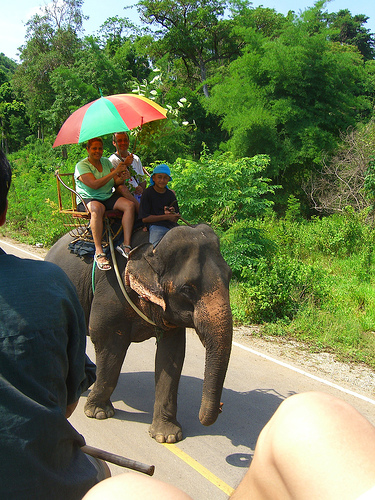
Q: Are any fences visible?
A: No, there are no fences.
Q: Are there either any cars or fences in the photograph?
A: No, there are no fences or cars.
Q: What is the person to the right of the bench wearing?
A: The person is wearing a cap.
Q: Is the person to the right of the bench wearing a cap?
A: Yes, the person is wearing a cap.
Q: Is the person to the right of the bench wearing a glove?
A: No, the person is wearing a cap.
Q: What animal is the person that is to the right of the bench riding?
A: The person is riding an elephant.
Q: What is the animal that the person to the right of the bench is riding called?
A: The animal is an elephant.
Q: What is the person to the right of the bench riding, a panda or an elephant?
A: The person is riding an elephant.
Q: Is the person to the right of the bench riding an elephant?
A: Yes, the person is riding an elephant.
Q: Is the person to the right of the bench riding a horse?
A: No, the person is riding an elephant.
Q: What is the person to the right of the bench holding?
A: The person is holding the stick.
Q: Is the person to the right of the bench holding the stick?
A: Yes, the person is holding the stick.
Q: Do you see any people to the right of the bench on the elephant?
A: Yes, there is a person to the right of the bench.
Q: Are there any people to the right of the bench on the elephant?
A: Yes, there is a person to the right of the bench.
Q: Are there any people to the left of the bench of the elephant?
A: No, the person is to the right of the bench.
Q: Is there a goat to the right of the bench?
A: No, there is a person to the right of the bench.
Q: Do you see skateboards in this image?
A: No, there are no skateboards.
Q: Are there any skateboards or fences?
A: No, there are no skateboards or fences.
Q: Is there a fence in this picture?
A: No, there are no fences.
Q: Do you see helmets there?
A: No, there are no helmets.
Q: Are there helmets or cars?
A: No, there are no helmets or cars.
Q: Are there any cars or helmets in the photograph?
A: No, there are no helmets or cars.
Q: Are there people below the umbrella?
A: Yes, there is a person below the umbrella.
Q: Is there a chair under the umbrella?
A: No, there is a person under the umbrella.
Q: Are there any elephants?
A: Yes, there is an elephant.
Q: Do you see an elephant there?
A: Yes, there is an elephant.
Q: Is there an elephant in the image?
A: Yes, there is an elephant.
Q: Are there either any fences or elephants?
A: Yes, there is an elephant.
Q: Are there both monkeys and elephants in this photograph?
A: No, there is an elephant but no monkeys.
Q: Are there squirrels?
A: No, there are no squirrels.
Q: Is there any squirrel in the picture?
A: No, there are no squirrels.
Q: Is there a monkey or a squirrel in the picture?
A: No, there are no squirrels or monkeys.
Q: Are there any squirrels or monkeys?
A: No, there are no squirrels or monkeys.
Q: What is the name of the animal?
A: The animal is an elephant.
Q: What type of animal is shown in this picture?
A: The animal is an elephant.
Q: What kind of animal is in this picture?
A: The animal is an elephant.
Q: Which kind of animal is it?
A: The animal is an elephant.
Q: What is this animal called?
A: That is an elephant.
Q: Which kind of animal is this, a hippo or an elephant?
A: That is an elephant.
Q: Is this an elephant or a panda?
A: This is an elephant.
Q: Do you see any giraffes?
A: No, there are no giraffes.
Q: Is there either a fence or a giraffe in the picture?
A: No, there are no giraffes or fences.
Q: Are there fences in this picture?
A: No, there are no fences.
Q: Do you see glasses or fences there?
A: No, there are no fences or glasses.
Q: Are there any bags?
A: No, there are no bags.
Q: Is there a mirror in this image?
A: No, there are no mirrors.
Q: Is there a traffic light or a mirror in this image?
A: No, there are no mirrors or traffic lights.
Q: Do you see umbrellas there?
A: Yes, there is an umbrella.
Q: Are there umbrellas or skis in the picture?
A: Yes, there is an umbrella.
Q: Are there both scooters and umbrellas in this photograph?
A: No, there is an umbrella but no scooters.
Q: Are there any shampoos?
A: No, there are no shampoos.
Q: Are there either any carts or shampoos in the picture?
A: No, there are no shampoos or carts.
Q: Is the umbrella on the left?
A: Yes, the umbrella is on the left of the image.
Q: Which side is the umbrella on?
A: The umbrella is on the left of the image.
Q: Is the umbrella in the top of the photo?
A: Yes, the umbrella is in the top of the image.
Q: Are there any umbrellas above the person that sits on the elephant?
A: Yes, there is an umbrella above the person.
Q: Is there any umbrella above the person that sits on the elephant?
A: Yes, there is an umbrella above the person.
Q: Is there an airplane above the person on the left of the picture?
A: No, there is an umbrella above the person.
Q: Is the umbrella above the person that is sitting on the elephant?
A: Yes, the umbrella is above the person.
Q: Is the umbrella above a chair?
A: No, the umbrella is above the person.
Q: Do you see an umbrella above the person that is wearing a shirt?
A: Yes, there is an umbrella above the person.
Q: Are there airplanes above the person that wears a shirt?
A: No, there is an umbrella above the person.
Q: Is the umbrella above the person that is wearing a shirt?
A: Yes, the umbrella is above the person.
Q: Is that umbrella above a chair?
A: No, the umbrella is above the person.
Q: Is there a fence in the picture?
A: No, there are no fences.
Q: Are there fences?
A: No, there are no fences.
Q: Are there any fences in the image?
A: No, there are no fences.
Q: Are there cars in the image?
A: No, there are no cars.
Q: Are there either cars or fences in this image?
A: No, there are no cars or fences.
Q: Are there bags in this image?
A: No, there are no bags.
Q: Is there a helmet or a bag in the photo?
A: No, there are no bags or helmets.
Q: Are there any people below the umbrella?
A: Yes, there is a person below the umbrella.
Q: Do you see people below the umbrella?
A: Yes, there is a person below the umbrella.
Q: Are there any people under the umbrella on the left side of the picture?
A: Yes, there is a person under the umbrella.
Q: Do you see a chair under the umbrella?
A: No, there is a person under the umbrella.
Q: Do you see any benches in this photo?
A: Yes, there is a bench.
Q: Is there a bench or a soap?
A: Yes, there is a bench.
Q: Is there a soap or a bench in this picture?
A: Yes, there is a bench.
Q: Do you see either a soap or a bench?
A: Yes, there is a bench.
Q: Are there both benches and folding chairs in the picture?
A: No, there is a bench but no folding chairs.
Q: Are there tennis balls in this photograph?
A: No, there are no tennis balls.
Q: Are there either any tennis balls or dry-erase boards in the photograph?
A: No, there are no tennis balls or dry-erase boards.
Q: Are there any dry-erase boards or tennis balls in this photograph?
A: No, there are no tennis balls or dry-erase boards.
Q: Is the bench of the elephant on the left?
A: Yes, the bench is on the left of the image.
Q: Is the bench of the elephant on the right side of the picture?
A: No, the bench is on the left of the image.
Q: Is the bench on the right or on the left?
A: The bench is on the left of the image.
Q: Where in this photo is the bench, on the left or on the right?
A: The bench is on the left of the image.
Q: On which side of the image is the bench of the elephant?
A: The bench is on the left of the image.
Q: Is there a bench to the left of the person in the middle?
A: Yes, there is a bench to the left of the person.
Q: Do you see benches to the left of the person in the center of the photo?
A: Yes, there is a bench to the left of the person.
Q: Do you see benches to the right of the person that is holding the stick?
A: No, the bench is to the left of the person.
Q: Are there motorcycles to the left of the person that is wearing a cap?
A: No, there is a bench to the left of the person.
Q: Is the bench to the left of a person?
A: Yes, the bench is to the left of a person.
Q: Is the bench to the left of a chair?
A: No, the bench is to the left of a person.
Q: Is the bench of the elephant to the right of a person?
A: No, the bench is to the left of a person.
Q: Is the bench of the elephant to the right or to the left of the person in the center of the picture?
A: The bench is to the left of the person.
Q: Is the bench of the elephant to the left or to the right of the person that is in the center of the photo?
A: The bench is to the left of the person.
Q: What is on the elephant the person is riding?
A: The bench is on the elephant.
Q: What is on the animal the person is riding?
A: The bench is on the elephant.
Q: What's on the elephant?
A: The bench is on the elephant.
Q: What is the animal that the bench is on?
A: The animal is an elephant.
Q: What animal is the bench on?
A: The bench is on the elephant.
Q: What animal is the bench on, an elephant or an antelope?
A: The bench is on an elephant.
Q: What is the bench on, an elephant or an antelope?
A: The bench is on an elephant.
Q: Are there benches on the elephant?
A: Yes, there is a bench on the elephant.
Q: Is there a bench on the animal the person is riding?
A: Yes, there is a bench on the elephant.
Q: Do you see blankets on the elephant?
A: No, there is a bench on the elephant.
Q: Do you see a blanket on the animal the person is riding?
A: No, there is a bench on the elephant.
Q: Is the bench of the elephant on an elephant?
A: Yes, the bench is on an elephant.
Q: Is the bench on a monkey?
A: No, the bench is on an elephant.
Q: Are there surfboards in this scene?
A: No, there are no surfboards.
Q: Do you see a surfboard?
A: No, there are no surfboards.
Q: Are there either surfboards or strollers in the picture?
A: No, there are no surfboards or strollers.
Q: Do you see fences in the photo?
A: No, there are no fences.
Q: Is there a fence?
A: No, there are no fences.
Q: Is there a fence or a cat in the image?
A: No, there are no fences or cats.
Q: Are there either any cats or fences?
A: No, there are no fences or cats.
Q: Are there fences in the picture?
A: No, there are no fences.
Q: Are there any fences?
A: No, there are no fences.